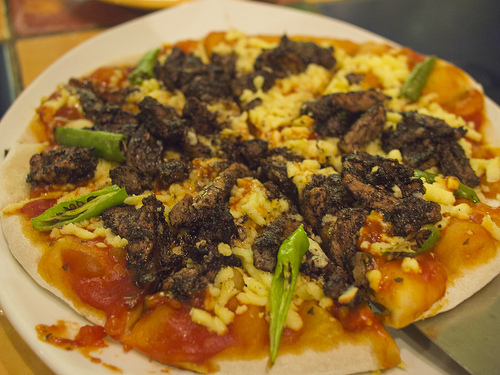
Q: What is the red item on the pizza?
A: Tomato.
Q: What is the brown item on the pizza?
A: Meat.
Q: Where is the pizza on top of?
A: Table.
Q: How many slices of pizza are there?
A: 6.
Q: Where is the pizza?
A: On the plate.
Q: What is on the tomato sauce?
A: Cheese.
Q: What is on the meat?
A: Vegetables.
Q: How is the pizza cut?
A: Into slices.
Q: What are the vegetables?
A: Green peppers.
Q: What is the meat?
A: Beef.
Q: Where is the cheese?
A: On the sauce.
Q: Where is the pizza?
A: On plate.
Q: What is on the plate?
A: Pizza.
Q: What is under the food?
A: A plate.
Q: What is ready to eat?
A: The food.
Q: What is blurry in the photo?
A: The background.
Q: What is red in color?
A: Tomato sauce.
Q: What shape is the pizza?
A: Round.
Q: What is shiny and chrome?
A: Surface.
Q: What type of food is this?
A: Pizza.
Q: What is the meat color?
A: Brown.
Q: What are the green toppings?
A: Peppers.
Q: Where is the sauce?
A: On the bottom.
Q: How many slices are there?
A: 6.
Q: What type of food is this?
A: Pizza.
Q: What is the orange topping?
A: Cheese.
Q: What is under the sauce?
A: Dough.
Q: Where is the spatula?
A: Under the pizza.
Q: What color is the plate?
A: White.